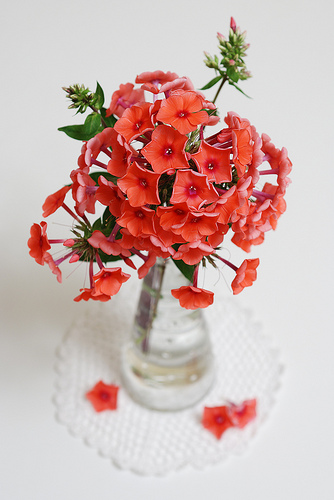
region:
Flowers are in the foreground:
[35, 73, 298, 316]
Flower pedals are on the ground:
[77, 369, 267, 453]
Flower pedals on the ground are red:
[65, 368, 261, 445]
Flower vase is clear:
[108, 242, 224, 415]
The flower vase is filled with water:
[5, 4, 316, 423]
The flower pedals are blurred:
[42, 355, 297, 481]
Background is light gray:
[30, 5, 152, 55]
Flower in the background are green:
[205, 6, 266, 92]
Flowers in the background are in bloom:
[197, 16, 275, 86]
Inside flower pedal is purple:
[187, 184, 196, 195]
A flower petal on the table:
[85, 377, 122, 415]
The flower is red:
[86, 379, 120, 416]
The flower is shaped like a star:
[84, 380, 122, 414]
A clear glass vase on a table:
[122, 250, 220, 405]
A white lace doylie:
[64, 278, 288, 479]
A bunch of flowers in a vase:
[28, 8, 299, 307]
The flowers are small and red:
[31, 62, 299, 300]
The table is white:
[0, 1, 332, 496]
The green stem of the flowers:
[129, 263, 168, 351]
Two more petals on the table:
[201, 396, 258, 441]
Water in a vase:
[129, 262, 210, 403]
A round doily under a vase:
[48, 290, 284, 461]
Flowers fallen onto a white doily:
[195, 391, 261, 442]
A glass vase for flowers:
[135, 249, 208, 366]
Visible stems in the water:
[128, 253, 168, 334]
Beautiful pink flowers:
[83, 110, 269, 266]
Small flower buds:
[58, 83, 90, 106]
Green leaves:
[61, 109, 101, 137]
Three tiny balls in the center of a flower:
[162, 144, 173, 153]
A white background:
[22, 2, 167, 51]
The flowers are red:
[36, 63, 285, 301]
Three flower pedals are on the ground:
[79, 374, 273, 451]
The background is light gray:
[2, 11, 169, 61]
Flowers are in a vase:
[81, 200, 250, 420]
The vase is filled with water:
[100, 222, 240, 421]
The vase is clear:
[91, 234, 256, 421]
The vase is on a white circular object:
[42, 282, 315, 486]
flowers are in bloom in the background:
[200, 9, 265, 92]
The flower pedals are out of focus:
[70, 366, 281, 446]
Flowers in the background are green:
[55, 76, 107, 126]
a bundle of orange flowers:
[131, 139, 243, 237]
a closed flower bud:
[64, 86, 110, 133]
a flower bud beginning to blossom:
[210, 13, 257, 78]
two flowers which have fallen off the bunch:
[202, 397, 255, 432]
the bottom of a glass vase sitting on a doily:
[120, 366, 205, 430]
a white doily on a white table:
[112, 416, 185, 462]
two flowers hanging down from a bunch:
[80, 257, 130, 299]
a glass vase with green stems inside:
[125, 286, 218, 390]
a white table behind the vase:
[25, 6, 151, 64]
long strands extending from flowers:
[212, 268, 230, 285]